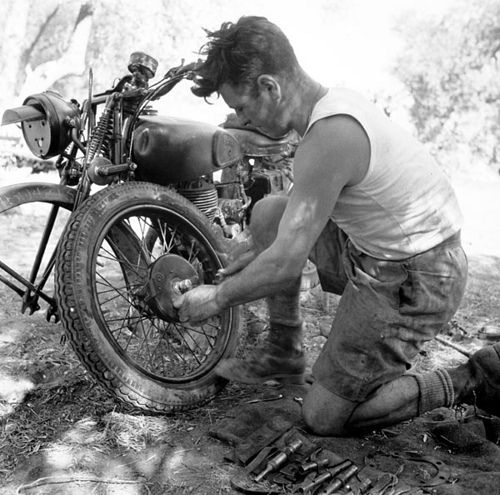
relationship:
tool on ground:
[349, 475, 374, 494] [4, 162, 496, 494]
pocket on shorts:
[401, 267, 453, 316] [314, 219, 466, 399]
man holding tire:
[174, 34, 487, 447] [46, 175, 247, 419]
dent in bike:
[134, 127, 154, 157] [0, 52, 298, 411]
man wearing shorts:
[174, 34, 487, 447] [310, 218, 481, 391]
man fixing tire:
[174, 34, 487, 447] [50, 175, 248, 414]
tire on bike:
[50, 175, 248, 414] [0, 49, 302, 412]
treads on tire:
[50, 202, 93, 327] [46, 175, 247, 419]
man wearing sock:
[174, 34, 487, 447] [408, 367, 457, 417]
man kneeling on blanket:
[174, 34, 487, 447] [207, 337, 499, 493]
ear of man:
[255, 75, 282, 101] [174, 34, 487, 447]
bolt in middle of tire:
[178, 276, 195, 295] [50, 175, 248, 414]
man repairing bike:
[174, 34, 487, 447] [0, 52, 298, 411]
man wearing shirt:
[174, 34, 487, 447] [303, 86, 465, 241]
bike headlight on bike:
[0, 90, 83, 165] [0, 52, 298, 411]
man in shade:
[174, 34, 487, 447] [49, 390, 230, 478]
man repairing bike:
[174, 34, 487, 447] [15, 57, 252, 420]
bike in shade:
[15, 57, 252, 420] [49, 390, 230, 478]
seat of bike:
[184, 111, 301, 175] [0, 52, 298, 411]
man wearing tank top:
[185, 5, 499, 430] [308, 83, 464, 263]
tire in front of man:
[46, 175, 247, 419] [174, 34, 487, 447]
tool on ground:
[241, 432, 374, 494] [4, 162, 496, 494]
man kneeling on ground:
[174, 34, 487, 447] [9, 210, 498, 492]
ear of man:
[249, 75, 292, 100] [174, 34, 487, 447]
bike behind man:
[0, 52, 298, 411] [174, 34, 487, 447]